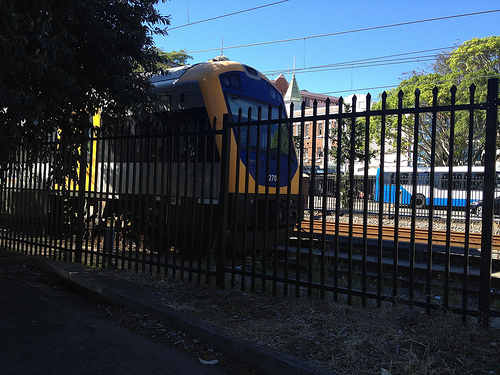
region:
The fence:
[277, 112, 468, 370]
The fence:
[274, 71, 399, 335]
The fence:
[341, 170, 446, 372]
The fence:
[314, 165, 381, 330]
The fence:
[308, 52, 438, 306]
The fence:
[370, 141, 467, 349]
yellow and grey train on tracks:
[97, 47, 324, 257]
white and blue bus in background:
[348, 152, 490, 232]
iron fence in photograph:
[15, 131, 497, 296]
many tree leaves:
[12, 1, 180, 159]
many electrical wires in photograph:
[168, 5, 492, 125]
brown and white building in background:
[270, 65, 395, 172]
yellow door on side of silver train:
[22, 91, 119, 209]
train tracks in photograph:
[288, 207, 498, 311]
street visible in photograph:
[15, 224, 222, 372]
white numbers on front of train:
[240, 165, 324, 210]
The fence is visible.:
[351, 202, 415, 317]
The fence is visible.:
[357, 201, 395, 259]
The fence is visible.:
[364, 162, 452, 299]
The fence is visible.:
[378, 180, 423, 261]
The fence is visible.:
[327, 191, 395, 291]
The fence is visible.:
[397, 178, 481, 270]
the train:
[105, 48, 343, 367]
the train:
[82, 22, 301, 242]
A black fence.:
[215, 95, 499, 325]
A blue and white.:
[364, 150, 499, 212]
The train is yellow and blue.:
[7, 47, 314, 272]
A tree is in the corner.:
[6, 2, 173, 162]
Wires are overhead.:
[243, 5, 399, 65]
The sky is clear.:
[273, 7, 342, 33]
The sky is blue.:
[275, 5, 354, 30]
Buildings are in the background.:
[266, 61, 433, 166]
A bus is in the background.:
[368, 153, 498, 223]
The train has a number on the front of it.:
[239, 168, 294, 192]